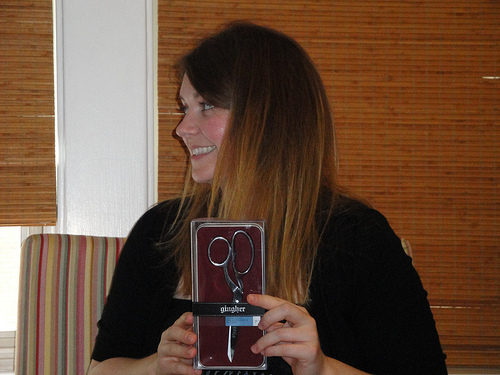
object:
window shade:
[0, 0, 59, 228]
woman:
[92, 22, 452, 374]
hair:
[157, 23, 341, 305]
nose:
[174, 115, 201, 140]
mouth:
[183, 142, 220, 160]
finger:
[245, 291, 288, 309]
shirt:
[84, 189, 447, 374]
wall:
[52, 0, 160, 238]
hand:
[247, 293, 328, 375]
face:
[174, 73, 233, 180]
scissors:
[205, 230, 254, 363]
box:
[190, 217, 269, 371]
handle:
[207, 229, 257, 277]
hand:
[156, 311, 201, 374]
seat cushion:
[16, 232, 121, 374]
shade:
[158, 1, 500, 374]